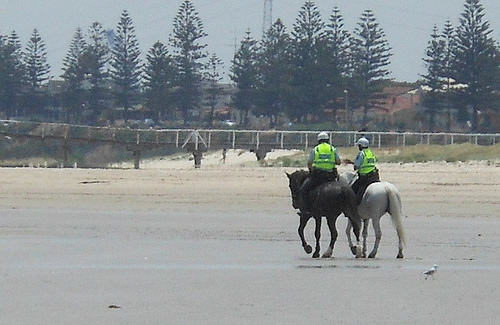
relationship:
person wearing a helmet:
[352, 137, 381, 200] [358, 135, 369, 148]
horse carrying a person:
[342, 171, 407, 260] [352, 137, 381, 200]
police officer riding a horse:
[309, 130, 342, 177] [284, 168, 361, 258]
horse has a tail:
[284, 168, 361, 258] [341, 185, 362, 239]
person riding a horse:
[352, 137, 381, 200] [342, 171, 407, 260]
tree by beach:
[165, 1, 210, 129] [4, 156, 499, 325]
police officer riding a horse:
[298, 131, 342, 216] [284, 168, 361, 258]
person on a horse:
[352, 137, 381, 200] [342, 171, 407, 260]